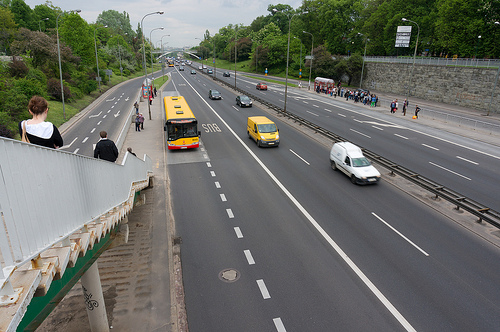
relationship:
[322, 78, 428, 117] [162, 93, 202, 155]
people in bus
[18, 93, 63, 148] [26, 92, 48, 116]
female in hair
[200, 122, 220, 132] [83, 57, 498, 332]
word in road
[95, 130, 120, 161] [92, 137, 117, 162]
male wearing black outerwear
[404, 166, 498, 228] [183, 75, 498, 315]
guardrail in center of road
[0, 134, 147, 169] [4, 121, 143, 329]
rail on steps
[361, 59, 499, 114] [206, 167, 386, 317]
wall on street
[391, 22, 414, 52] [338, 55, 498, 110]
banner above wall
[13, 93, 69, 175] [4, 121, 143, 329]
female on steps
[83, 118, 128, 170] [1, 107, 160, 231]
male on steps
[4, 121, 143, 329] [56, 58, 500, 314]
steps next to highway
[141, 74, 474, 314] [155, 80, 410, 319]
highway divided into lanes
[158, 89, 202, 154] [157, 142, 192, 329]
bus at curb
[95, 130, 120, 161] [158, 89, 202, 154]
male for bus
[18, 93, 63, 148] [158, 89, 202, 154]
female for bus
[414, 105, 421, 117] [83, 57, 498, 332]
people at side of road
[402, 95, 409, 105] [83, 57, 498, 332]
person at side of road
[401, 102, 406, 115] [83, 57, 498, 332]
people at side of road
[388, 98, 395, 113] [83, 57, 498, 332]
person at side of road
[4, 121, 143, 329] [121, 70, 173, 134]
steps leading to bus stop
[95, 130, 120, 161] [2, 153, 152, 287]
male walks down stairway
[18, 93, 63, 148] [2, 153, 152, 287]
female walks down stairway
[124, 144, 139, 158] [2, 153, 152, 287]
person walks down stairway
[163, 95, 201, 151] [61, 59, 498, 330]
bus on street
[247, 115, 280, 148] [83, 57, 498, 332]
car on road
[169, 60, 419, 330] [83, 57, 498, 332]
line on road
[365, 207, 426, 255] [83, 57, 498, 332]
line on road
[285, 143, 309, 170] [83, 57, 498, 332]
line on road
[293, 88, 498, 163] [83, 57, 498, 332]
line on road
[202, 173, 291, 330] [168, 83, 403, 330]
dotted line on street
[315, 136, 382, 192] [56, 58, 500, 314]
car on highway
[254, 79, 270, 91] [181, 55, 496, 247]
car on street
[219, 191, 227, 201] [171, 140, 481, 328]
lines painted on highway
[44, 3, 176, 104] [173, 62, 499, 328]
street lights line lane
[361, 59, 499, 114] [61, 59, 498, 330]
wall next to street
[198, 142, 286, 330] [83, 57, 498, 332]
line painted on road